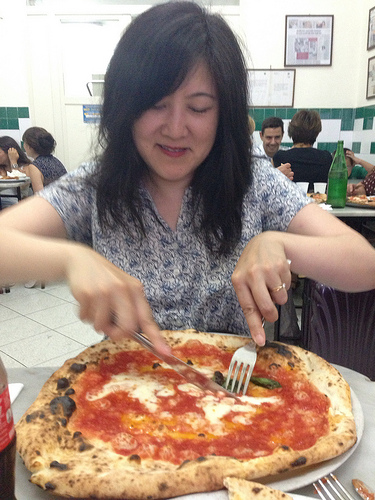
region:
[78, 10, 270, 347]
woman in a black and white top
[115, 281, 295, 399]
silver fork and knife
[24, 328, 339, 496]
large pizza with crispy crust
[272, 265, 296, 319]
gold ring on finger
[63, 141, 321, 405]
woman cutting pizza with fork and knife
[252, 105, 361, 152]
green and white tile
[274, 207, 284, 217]
blue design on shirt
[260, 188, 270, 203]
blue design on shirt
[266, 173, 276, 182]
blue design on shirt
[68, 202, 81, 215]
blue design on shirt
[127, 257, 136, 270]
blue design on shirt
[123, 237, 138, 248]
blue design on shirt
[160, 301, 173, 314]
blue design on shirt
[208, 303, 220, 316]
blue design on shirt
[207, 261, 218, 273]
blue design on shirt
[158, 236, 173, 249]
blue design on shirt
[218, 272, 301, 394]
woman holding a fork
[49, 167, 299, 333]
woman wearing a parsley shirt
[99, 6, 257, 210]
woman with black hair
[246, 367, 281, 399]
basil on a pizza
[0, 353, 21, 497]
bottle of soda on a table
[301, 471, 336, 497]
fork on a table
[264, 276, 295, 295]
woman wearing a ring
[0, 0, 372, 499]
Woman cutting pizza with a knife and fork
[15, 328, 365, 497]
Pizza on a plate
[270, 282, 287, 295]
Ring on woman's finger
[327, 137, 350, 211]
Green bottle on the table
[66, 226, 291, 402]
Knife and fork in woman's hands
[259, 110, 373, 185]
People seated at back table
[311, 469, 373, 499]
Tip of dirty knife and fork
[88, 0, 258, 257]
Smiling girl with black hair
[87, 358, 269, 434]
Cheese on a pizza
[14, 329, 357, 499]
Meatless pizza on a plate.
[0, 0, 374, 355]
Black-haired woman slicing pizza.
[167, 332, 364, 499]
White plate holding a pizza.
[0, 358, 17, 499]
Plastic bottle of soda pop.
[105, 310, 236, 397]
Metal knife held by woman.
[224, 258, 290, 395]
Metal fork held by woman.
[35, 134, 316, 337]
Blue-and-white patterned blouse worn on a woman.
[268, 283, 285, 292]
Gold ring with diamond on woman's finger.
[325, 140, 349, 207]
Green bottle of fluid on table.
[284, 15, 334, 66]
Black-framed item on wall.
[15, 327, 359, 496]
the pizza is whole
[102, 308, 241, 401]
the silver butter knife on the pizza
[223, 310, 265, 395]
the silver fork has prongs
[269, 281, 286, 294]
the thin gold ring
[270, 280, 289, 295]
woman wearing a wedding ring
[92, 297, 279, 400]
woman holding knife and fork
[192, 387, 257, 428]
white cheese on the pizza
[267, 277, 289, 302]
woman wearing a engagement ring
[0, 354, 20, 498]
soda bottle on the table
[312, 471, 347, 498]
fork on the table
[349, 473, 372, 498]
knife on the table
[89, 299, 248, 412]
knife in the pizza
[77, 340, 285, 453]
tomato and cheese on the pizza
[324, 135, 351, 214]
green bottle on the shirt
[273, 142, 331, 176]
woman wearing a black shirt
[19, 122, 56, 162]
woman with a bun and her hair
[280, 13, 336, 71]
picture hanging on the wall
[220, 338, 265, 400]
silver metal dining fork